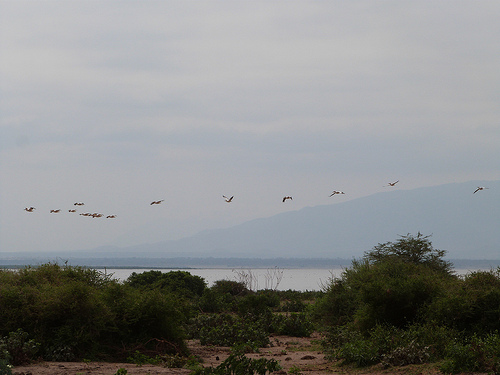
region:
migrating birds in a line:
[20, 186, 498, 210]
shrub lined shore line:
[10, 248, 477, 335]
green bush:
[322, 238, 464, 333]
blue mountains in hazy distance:
[185, 176, 495, 255]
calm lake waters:
[197, 252, 350, 291]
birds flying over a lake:
[16, 183, 435, 295]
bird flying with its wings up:
[214, 186, 251, 226]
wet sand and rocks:
[267, 331, 308, 373]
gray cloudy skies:
[40, 35, 382, 154]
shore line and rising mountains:
[147, 221, 314, 283]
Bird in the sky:
[273, 183, 306, 209]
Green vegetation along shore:
[313, 230, 496, 365]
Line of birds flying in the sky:
[18, 160, 496, 233]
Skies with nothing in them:
[28, 30, 498, 160]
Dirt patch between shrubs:
[180, 329, 322, 374]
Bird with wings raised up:
[203, 186, 241, 208]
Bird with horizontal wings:
[138, 190, 163, 210]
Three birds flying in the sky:
[212, 188, 360, 212]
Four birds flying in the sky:
[213, 174, 427, 206]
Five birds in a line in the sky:
[213, 167, 497, 223]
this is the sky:
[131, 27, 309, 119]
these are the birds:
[13, 197, 117, 224]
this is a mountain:
[274, 212, 367, 249]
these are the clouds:
[216, 69, 252, 101]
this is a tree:
[357, 249, 441, 326]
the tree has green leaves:
[375, 276, 394, 293]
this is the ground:
[283, 337, 316, 368]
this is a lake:
[287, 270, 319, 284]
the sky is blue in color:
[181, 130, 209, 145]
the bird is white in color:
[222, 192, 231, 203]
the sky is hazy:
[10, 67, 494, 278]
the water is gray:
[218, 263, 343, 294]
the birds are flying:
[17, 170, 499, 227]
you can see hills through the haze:
[261, 167, 498, 264]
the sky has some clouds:
[115, 96, 452, 178]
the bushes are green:
[310, 254, 494, 370]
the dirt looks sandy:
[20, 334, 346, 374]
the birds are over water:
[17, 184, 197, 294]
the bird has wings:
[217, 191, 246, 208]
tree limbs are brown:
[113, 328, 186, 372]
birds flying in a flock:
[26, 175, 495, 223]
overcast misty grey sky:
[0, 1, 498, 278]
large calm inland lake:
[7, 269, 499, 298]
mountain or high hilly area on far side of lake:
[15, 176, 496, 266]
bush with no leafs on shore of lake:
[243, 266, 292, 293]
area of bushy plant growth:
[308, 235, 496, 360]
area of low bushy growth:
[5, 260, 196, 360]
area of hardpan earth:
[12, 340, 407, 372]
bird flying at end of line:
[467, 177, 490, 199]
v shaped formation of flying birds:
[23, 195, 149, 229]